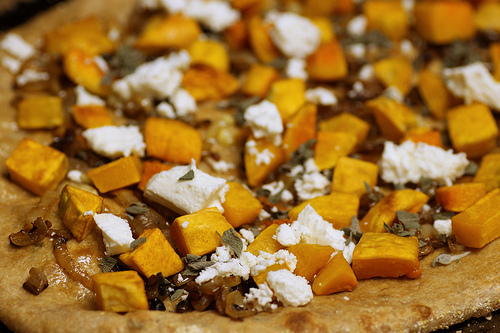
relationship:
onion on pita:
[47, 228, 117, 307] [3, 3, 499, 332]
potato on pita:
[126, 225, 185, 277] [3, 3, 499, 332]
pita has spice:
[3, 3, 499, 332] [217, 226, 248, 258]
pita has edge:
[3, 3, 499, 332] [348, 250, 495, 330]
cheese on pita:
[312, 252, 362, 301] [3, 3, 499, 332]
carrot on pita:
[89, 155, 144, 190] [3, 3, 499, 332]